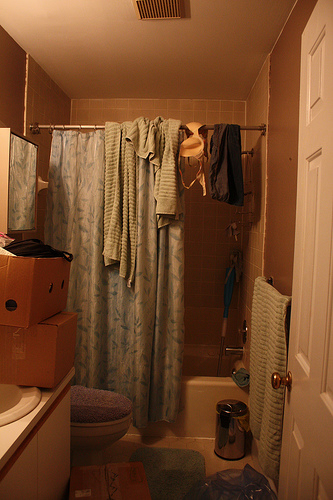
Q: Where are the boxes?
A: On the sink.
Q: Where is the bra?
A: Hanging on a shower rod.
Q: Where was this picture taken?
A: In a bathroom.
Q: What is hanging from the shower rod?
A: Shower curtain and laundry.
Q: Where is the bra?
A: Hanging from the shower rod.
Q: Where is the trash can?
A: By the shower.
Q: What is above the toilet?
A: Medicine cabinet.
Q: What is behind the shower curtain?
A: Bathtub.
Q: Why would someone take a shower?
A: To get clean.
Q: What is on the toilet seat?
A: Toilet cover.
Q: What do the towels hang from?
A: Metal rod.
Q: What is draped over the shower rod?
A: Towels and underwear.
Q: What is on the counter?
A: Boxes.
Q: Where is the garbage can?
A: On the floor.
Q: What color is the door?
A: White.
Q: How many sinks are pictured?
A: One.